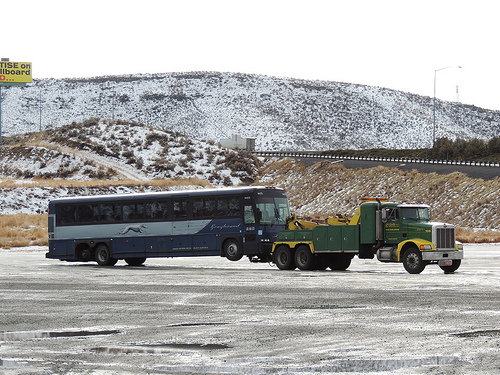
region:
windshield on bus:
[248, 198, 291, 227]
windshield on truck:
[400, 205, 428, 220]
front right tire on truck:
[401, 249, 421, 271]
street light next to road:
[431, 59, 468, 156]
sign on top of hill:
[2, 60, 35, 84]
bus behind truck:
[42, 186, 284, 263]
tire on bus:
[223, 238, 243, 259]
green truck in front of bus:
[275, 196, 463, 273]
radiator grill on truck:
[437, 226, 458, 251]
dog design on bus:
[115, 223, 157, 239]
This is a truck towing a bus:
[16, 80, 468, 335]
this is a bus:
[40, 183, 290, 310]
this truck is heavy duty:
[275, 194, 493, 276]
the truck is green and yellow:
[319, 193, 490, 253]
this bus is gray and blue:
[42, 167, 319, 277]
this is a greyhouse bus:
[41, 189, 241, 281]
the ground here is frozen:
[120, 282, 445, 357]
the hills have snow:
[117, 68, 392, 107]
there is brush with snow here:
[45, 107, 262, 182]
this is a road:
[318, 127, 464, 184]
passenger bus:
[51, 163, 269, 275]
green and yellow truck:
[296, 189, 470, 284]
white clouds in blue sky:
[29, 17, 70, 44]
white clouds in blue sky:
[70, 23, 128, 67]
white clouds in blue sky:
[103, 6, 153, 53]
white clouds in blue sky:
[189, 10, 227, 48]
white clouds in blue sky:
[249, 10, 287, 47]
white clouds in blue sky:
[300, 11, 342, 59]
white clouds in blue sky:
[363, 9, 391, 47]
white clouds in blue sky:
[390, 13, 455, 51]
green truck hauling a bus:
[25, 167, 495, 297]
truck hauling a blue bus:
[31, 145, 476, 286]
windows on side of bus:
[54, 199, 184, 223]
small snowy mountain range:
[11, 56, 491, 165]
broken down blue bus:
[26, 171, 291, 285]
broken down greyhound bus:
[39, 176, 331, 283]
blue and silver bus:
[42, 185, 287, 262]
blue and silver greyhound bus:
[43, 186, 293, 281]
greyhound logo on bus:
[114, 217, 150, 239]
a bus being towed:
[22, 96, 443, 367]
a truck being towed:
[49, 52, 497, 361]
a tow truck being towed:
[58, 119, 425, 371]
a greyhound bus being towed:
[52, 128, 461, 294]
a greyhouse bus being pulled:
[50, 130, 490, 306]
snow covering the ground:
[92, 16, 462, 229]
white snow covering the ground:
[102, 62, 479, 188]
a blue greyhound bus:
[35, 108, 336, 283]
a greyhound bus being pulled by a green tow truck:
[57, 159, 479, 287]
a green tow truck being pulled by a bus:
[43, 141, 490, 214]